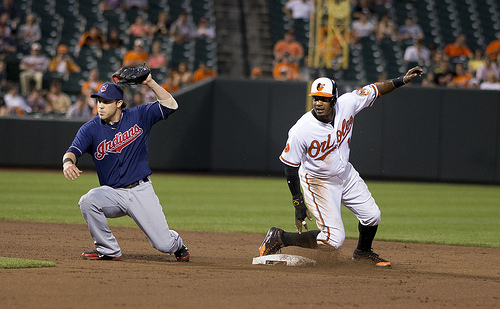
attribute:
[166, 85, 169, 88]
shirt — orange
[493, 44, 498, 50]
shirt — orange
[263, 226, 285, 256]
shoe — orange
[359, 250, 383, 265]
shoe — orange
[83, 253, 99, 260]
shoe — red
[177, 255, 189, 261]
shoe — red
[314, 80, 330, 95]
hat — white, orange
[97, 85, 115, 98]
hat — blue, red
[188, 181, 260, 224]
field — manicured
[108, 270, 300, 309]
mound — green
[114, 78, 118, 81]
marking — orange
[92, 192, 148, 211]
pants — gray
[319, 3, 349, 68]
tower — yellow